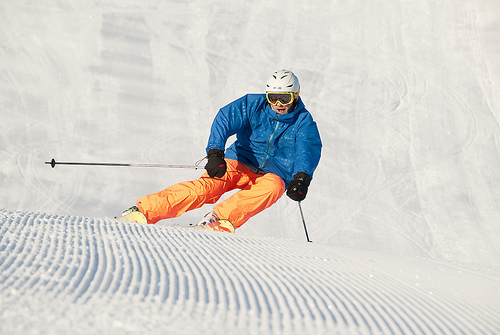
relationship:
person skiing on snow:
[184, 59, 331, 207] [358, 49, 446, 163]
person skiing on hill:
[184, 59, 331, 207] [370, 42, 443, 109]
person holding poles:
[184, 59, 331, 207] [40, 153, 199, 174]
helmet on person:
[260, 65, 302, 95] [184, 59, 331, 207]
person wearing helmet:
[184, 59, 331, 207] [260, 65, 302, 95]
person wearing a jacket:
[184, 59, 331, 207] [213, 114, 330, 165]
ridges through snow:
[96, 235, 166, 290] [358, 49, 446, 163]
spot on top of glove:
[218, 162, 227, 170] [202, 149, 229, 183]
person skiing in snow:
[184, 59, 331, 207] [358, 49, 446, 163]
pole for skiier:
[40, 153, 199, 174] [184, 59, 331, 207]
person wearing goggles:
[184, 59, 331, 207] [263, 89, 295, 106]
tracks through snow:
[120, 235, 194, 273] [358, 49, 446, 163]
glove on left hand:
[202, 149, 229, 183] [206, 150, 229, 178]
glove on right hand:
[288, 171, 312, 198] [287, 172, 311, 198]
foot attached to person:
[117, 198, 152, 223] [184, 59, 331, 207]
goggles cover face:
[263, 89, 295, 106] [265, 86, 302, 115]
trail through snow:
[96, 235, 166, 290] [358, 49, 446, 163]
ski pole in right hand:
[296, 202, 315, 243] [287, 172, 311, 198]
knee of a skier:
[197, 174, 224, 202] [184, 59, 331, 207]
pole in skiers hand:
[40, 153, 199, 174] [206, 150, 229, 178]